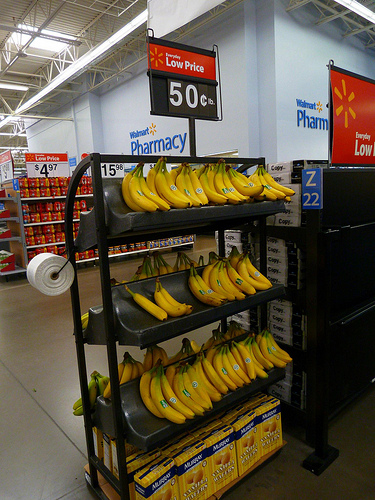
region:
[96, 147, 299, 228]
several bananas on a shelf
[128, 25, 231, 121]
a red and black sign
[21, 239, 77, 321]
roll of plastic bags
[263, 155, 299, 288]
several stacks of copy paper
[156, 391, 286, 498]
several boxes of cookies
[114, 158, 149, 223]
a bundle of bananas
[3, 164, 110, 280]
four metal shelves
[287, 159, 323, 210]
blue sign with white letters and numbers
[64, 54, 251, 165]
a wall with blue lettering on it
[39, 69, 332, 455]
three shelves of bananas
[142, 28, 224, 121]
a red black and white sign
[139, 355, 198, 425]
a bunch of yellow bananas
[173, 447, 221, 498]
a box of vanilla wafer cookies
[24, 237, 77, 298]
a roll of white plastic bags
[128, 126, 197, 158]
a Walmart Pharmacy sign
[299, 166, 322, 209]
a blue aisle number sign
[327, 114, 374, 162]
a red and white sign that says low prices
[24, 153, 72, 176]
a low price sign that says $4.97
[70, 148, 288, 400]
a shelf filled with yellow bananas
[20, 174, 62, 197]
Folgers coffee on a shelf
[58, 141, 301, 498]
Rack of bananas and vanilla wafers.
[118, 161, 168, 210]
Bunch of bananas.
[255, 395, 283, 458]
Box of vanilla wafers.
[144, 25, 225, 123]
Price sign.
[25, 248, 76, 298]
Bags to put produce in.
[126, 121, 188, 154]
Walmart Pharmacy sign.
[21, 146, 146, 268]
Racks of items with a price of $4.97.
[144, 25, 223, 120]
Price sign for bananas.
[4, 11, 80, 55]
Skylight on the roof.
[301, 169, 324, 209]
Sign for row Z22.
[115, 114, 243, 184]
walmart pharmacy sign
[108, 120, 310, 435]
bananas on a black rack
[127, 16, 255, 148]
.50 cent sign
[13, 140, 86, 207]
$4.97 sign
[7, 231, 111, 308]
white produce bags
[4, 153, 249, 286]
a rack of products for sale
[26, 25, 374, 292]
a picture of a walmart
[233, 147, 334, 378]
boxes of copy paper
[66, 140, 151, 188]
$15.98 sign in a walmart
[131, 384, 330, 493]
yellow and blue cardboard boxes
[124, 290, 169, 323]
a ripe banana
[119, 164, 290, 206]
a bunch of bananas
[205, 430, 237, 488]
packaged wafer cookies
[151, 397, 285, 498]
a row of packaged wafer cookies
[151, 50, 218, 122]
a price tag for bananas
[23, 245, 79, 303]
a bag for holding items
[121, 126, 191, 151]
a walmart pharmacy sign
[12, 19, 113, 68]
the roof of a building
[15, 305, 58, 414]
the gray floor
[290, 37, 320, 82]
a wall